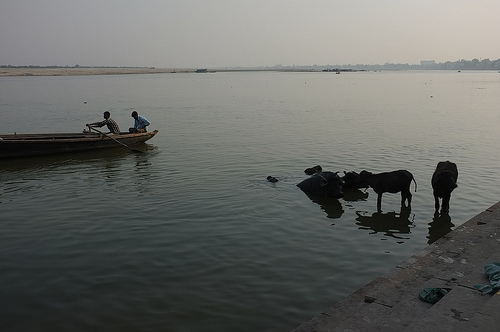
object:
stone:
[268, 174, 280, 183]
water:
[4, 73, 500, 322]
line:
[3, 55, 500, 74]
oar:
[89, 126, 137, 155]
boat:
[1, 130, 162, 153]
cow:
[354, 164, 416, 221]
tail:
[415, 176, 421, 195]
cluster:
[290, 198, 500, 329]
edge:
[2, 130, 160, 146]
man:
[83, 110, 125, 139]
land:
[1, 66, 204, 79]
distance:
[3, 0, 495, 109]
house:
[195, 67, 211, 71]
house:
[71, 62, 82, 72]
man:
[128, 109, 153, 135]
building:
[324, 67, 356, 72]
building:
[419, 59, 439, 63]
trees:
[260, 55, 500, 72]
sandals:
[421, 280, 456, 303]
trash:
[299, 161, 363, 201]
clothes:
[472, 258, 500, 296]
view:
[5, 5, 498, 78]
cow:
[295, 168, 346, 203]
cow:
[341, 166, 369, 192]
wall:
[291, 198, 500, 330]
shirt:
[131, 117, 152, 131]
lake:
[5, 65, 500, 321]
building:
[195, 66, 212, 77]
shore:
[3, 63, 203, 79]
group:
[293, 149, 462, 222]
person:
[88, 108, 122, 138]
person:
[127, 103, 156, 132]